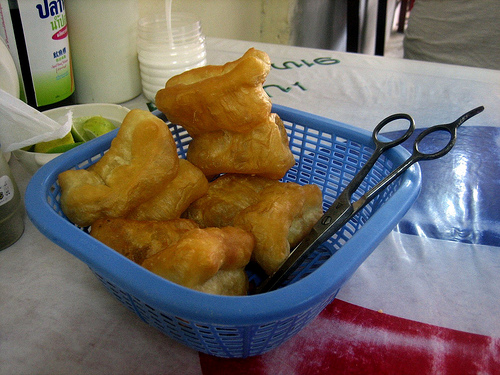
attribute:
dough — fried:
[55, 101, 214, 238]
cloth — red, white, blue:
[345, 259, 499, 357]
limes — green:
[45, 113, 107, 143]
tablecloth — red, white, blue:
[149, 23, 497, 370]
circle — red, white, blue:
[267, 109, 498, 364]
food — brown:
[27, 27, 474, 352]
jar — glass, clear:
[133, 19, 224, 92]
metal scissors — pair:
[265, 113, 455, 280]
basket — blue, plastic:
[16, 83, 428, 363]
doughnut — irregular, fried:
[152, 60, 340, 215]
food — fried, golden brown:
[58, 44, 323, 279]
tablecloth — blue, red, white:
[0, 35, 500, 373]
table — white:
[30, 25, 494, 272]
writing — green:
[268, 32, 345, 108]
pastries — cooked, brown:
[178, 152, 225, 210]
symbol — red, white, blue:
[196, 124, 498, 373]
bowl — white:
[66, 42, 438, 315]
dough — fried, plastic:
[70, 48, 324, 311]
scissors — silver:
[267, 102, 482, 292]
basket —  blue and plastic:
[111, 281, 337, 353]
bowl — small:
[13, 101, 134, 176]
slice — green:
[68, 115, 119, 145]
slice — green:
[25, 128, 73, 150]